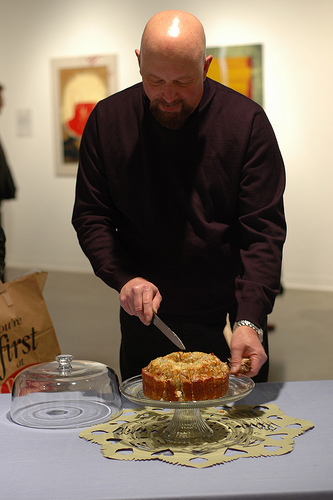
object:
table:
[1, 378, 332, 499]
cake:
[144, 348, 228, 398]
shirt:
[72, 77, 290, 322]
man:
[64, 8, 293, 396]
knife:
[148, 307, 187, 351]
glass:
[14, 353, 127, 427]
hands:
[118, 275, 270, 410]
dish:
[119, 338, 257, 446]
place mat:
[82, 396, 318, 474]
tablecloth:
[0, 383, 333, 498]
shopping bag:
[0, 260, 59, 396]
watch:
[232, 316, 271, 342]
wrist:
[227, 300, 269, 342]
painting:
[45, 58, 123, 179]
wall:
[2, 1, 332, 289]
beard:
[153, 94, 187, 127]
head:
[132, 5, 214, 113]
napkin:
[219, 313, 253, 374]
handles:
[1, 274, 15, 308]